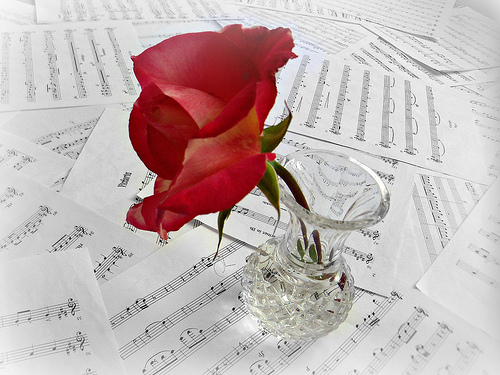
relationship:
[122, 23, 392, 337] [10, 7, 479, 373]
flower on music sheets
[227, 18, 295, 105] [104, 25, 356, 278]
edge of flower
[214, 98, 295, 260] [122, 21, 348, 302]
leaves of flower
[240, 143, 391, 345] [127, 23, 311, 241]
vase in rose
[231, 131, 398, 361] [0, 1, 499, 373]
vase in music sheets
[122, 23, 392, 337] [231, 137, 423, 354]
flower in vase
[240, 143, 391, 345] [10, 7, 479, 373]
vase on top of music sheets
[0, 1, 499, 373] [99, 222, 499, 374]
music sheets on paper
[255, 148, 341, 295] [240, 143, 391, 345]
stem inside vase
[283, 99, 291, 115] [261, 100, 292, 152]
bent tip of leaf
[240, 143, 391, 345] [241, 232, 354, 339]
vase filled with water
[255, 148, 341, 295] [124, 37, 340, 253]
stem from flower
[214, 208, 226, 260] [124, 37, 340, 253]
leaves from flower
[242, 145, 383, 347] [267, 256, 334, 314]
clear vase on water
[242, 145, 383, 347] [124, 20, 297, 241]
clear vase from flower